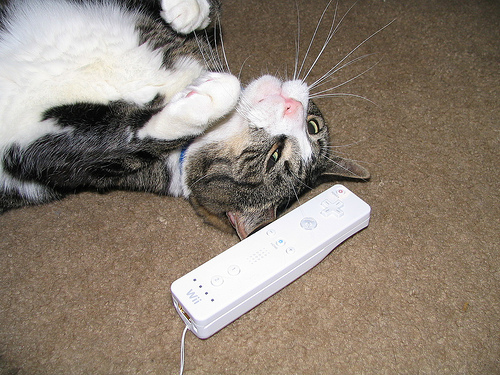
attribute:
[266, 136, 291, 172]
eye — green, black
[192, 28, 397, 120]
whiskers — white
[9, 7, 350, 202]
striped cat — black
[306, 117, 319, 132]
eye — brown, yellow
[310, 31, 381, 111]
whiskers — growing out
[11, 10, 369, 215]
cat — striped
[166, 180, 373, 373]
wiimote — white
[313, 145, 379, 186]
ear — pointy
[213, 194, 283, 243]
ear — pointy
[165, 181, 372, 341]
game controller — video game controller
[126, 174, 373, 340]
remote — white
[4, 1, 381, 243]
cat — upside down, striped, black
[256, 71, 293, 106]
mouth — white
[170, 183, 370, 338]
remote — white, Nintendo Wii mote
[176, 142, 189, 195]
collar — blue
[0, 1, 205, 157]
cat fur — white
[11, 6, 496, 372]
carpet — beige, light brown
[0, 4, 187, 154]
fur — white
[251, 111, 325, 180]
eyes — green